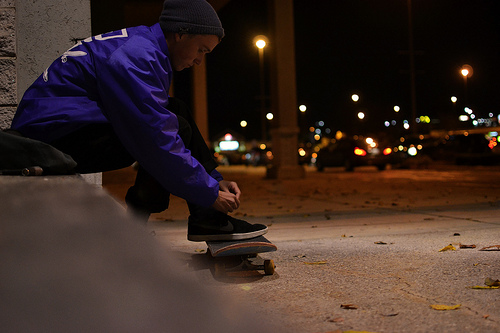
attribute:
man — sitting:
[10, 0, 269, 241]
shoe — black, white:
[186, 212, 269, 243]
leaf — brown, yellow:
[476, 240, 499, 252]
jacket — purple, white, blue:
[8, 21, 225, 209]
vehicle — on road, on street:
[314, 132, 395, 173]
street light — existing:
[250, 34, 269, 138]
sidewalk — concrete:
[104, 168, 499, 332]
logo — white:
[191, 218, 235, 232]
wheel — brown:
[211, 260, 227, 279]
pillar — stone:
[261, 1, 307, 183]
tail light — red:
[353, 144, 368, 158]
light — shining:
[251, 33, 270, 53]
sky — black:
[91, 1, 499, 136]